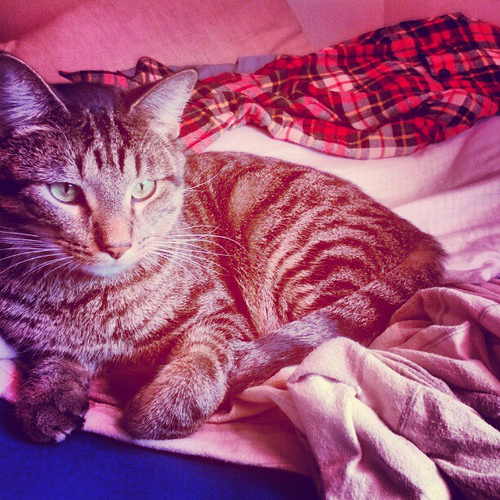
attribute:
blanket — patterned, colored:
[59, 12, 499, 160]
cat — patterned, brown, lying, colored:
[0, 50, 451, 445]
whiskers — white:
[0, 224, 250, 295]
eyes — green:
[48, 178, 158, 208]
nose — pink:
[103, 244, 130, 260]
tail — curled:
[229, 246, 446, 396]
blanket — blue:
[2, 395, 321, 498]